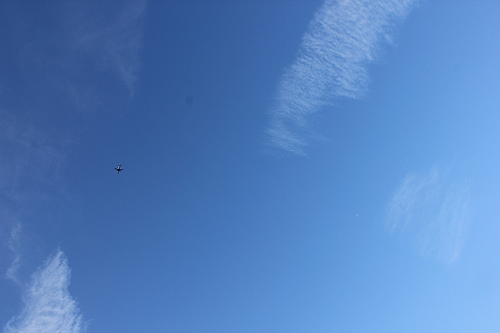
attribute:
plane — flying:
[113, 164, 123, 174]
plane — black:
[112, 160, 125, 175]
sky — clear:
[32, 9, 499, 323]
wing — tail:
[116, 162, 123, 167]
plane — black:
[110, 162, 130, 179]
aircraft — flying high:
[115, 162, 122, 172]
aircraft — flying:
[110, 161, 125, 178]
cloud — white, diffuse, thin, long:
[264, 4, 404, 160]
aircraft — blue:
[114, 160, 124, 175]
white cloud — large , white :
[264, 20, 385, 167]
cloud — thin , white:
[4, 245, 91, 331]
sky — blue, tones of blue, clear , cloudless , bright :
[1, 0, 493, 331]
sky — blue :
[208, 91, 330, 217]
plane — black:
[96, 159, 139, 183]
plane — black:
[115, 163, 125, 174]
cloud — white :
[262, 0, 417, 169]